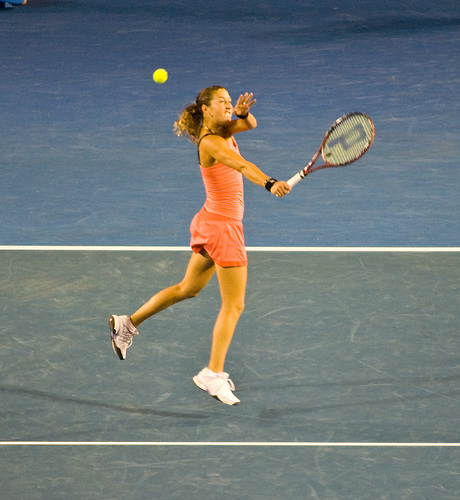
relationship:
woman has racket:
[107, 82, 378, 409] [271, 109, 378, 199]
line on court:
[1, 240, 459, 256] [1, 2, 456, 494]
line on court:
[1, 437, 459, 452] [1, 2, 456, 494]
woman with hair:
[107, 82, 378, 409] [172, 83, 236, 143]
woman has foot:
[107, 82, 378, 409] [189, 362, 245, 408]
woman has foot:
[107, 82, 378, 409] [106, 310, 143, 363]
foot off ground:
[189, 362, 245, 408] [1, 2, 456, 494]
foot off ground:
[106, 310, 143, 363] [1, 2, 456, 494]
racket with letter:
[271, 109, 378, 199] [326, 120, 368, 154]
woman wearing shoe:
[107, 82, 378, 409] [189, 362, 245, 408]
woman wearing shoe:
[107, 82, 378, 409] [106, 310, 143, 363]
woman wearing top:
[107, 82, 378, 409] [193, 130, 248, 223]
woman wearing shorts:
[107, 82, 378, 409] [184, 203, 252, 271]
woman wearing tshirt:
[107, 82, 378, 409] [193, 130, 248, 223]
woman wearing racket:
[107, 82, 378, 409] [271, 109, 378, 199]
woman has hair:
[107, 82, 378, 409] [172, 83, 236, 143]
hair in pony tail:
[172, 83, 236, 143] [174, 88, 206, 141]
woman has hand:
[107, 82, 378, 409] [267, 175, 292, 200]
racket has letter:
[271, 109, 378, 199] [326, 120, 368, 154]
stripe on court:
[1, 240, 459, 256] [1, 2, 456, 494]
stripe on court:
[1, 437, 459, 452] [1, 2, 456, 494]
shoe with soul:
[189, 362, 245, 408] [189, 374, 243, 416]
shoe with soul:
[106, 310, 143, 363] [103, 312, 129, 364]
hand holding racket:
[267, 175, 292, 200] [271, 109, 378, 199]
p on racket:
[326, 120, 368, 154] [271, 109, 378, 199]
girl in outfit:
[107, 82, 378, 409] [185, 136, 254, 270]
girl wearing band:
[107, 82, 378, 409] [263, 171, 279, 193]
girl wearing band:
[107, 82, 378, 409] [235, 108, 256, 122]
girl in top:
[107, 82, 378, 409] [193, 130, 248, 223]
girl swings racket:
[107, 82, 378, 409] [271, 109, 378, 199]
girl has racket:
[107, 82, 378, 409] [271, 109, 378, 199]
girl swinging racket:
[107, 82, 378, 409] [271, 109, 378, 199]